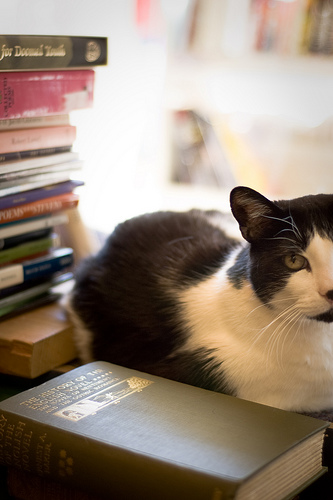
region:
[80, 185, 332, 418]
the cat is white and black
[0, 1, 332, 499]
the cat is besides books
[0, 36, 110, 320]
the books are stacked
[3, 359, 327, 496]
the large book is olive greeen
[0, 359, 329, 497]
the book is hard covered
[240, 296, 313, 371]
the cat has long whiskers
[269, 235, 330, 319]
the cat has a white face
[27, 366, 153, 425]
the book has gold lettering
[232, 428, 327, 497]
the book is thick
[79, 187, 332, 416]
the cat is sitting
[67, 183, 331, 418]
The cat is black and white.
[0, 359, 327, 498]
The book cover is light green.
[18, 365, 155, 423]
The book cover is embossed in gold leaf.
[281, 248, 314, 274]
The cat's eye is green.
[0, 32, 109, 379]
The books are not in focus.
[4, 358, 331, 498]
The book is rectangular.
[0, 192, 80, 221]
The book is orange.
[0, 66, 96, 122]
The book is red.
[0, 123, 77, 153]
The book is pink.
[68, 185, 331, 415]
The cat is lying down.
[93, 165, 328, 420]
a cat laing down inside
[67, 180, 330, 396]
a cat laying down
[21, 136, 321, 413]
a cat laying by books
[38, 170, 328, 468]
a cat next to books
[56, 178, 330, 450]
a white and black cat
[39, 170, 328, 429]
white and black cat laying down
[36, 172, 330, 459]
white and black cat laying down inside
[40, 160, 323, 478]
a black and white cat laying next to a book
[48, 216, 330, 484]
a book and a cat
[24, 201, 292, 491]
a cat and a book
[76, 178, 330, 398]
a cat facing forwards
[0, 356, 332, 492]
a book in front of the cat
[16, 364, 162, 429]
a title on the book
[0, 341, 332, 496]
the book is a history book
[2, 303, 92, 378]
a wooden shelf behind the cat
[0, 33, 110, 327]
a stack of books on the shelf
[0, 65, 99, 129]
a red book in the stack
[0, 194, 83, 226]
an orange book on the stack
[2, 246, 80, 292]
a blue and white book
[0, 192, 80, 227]
this is a poems book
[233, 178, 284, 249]
Cat has black ear.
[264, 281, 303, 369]
Cat has white whiskers.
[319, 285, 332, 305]
Tip of nose is black.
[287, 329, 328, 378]
Cat has white chest.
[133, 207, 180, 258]
Fur on cat's back is black.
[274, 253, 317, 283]
Cat has green eye.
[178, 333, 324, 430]
Cat is sitting behind book.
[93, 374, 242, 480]
Green cover on book.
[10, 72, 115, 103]
Pink book near top of stack.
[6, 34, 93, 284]
Stack of book near cat.